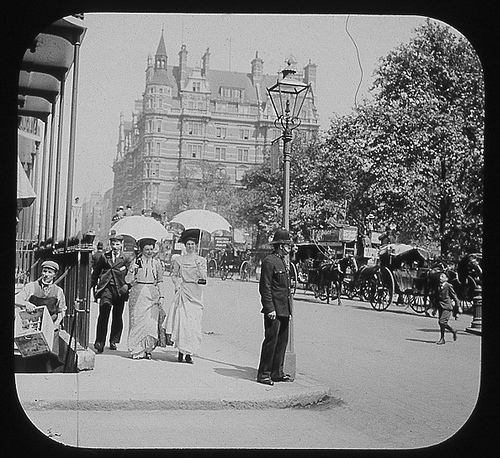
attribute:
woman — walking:
[125, 240, 163, 361]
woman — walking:
[170, 234, 206, 366]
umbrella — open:
[110, 215, 173, 241]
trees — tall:
[170, 17, 487, 253]